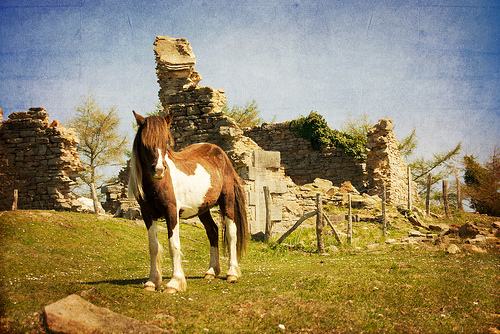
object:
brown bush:
[462, 145, 499, 217]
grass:
[161, 260, 323, 307]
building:
[0, 35, 417, 237]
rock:
[312, 178, 333, 191]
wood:
[262, 186, 271, 244]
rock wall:
[0, 107, 105, 215]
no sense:
[322, 131, 382, 159]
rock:
[397, 202, 500, 255]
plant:
[335, 246, 424, 316]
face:
[141, 126, 166, 165]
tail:
[218, 174, 249, 263]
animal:
[128, 110, 249, 294]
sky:
[0, 0, 499, 215]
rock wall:
[262, 139, 358, 187]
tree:
[341, 103, 464, 196]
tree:
[65, 86, 132, 214]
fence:
[262, 167, 464, 255]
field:
[0, 200, 499, 334]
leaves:
[273, 263, 366, 280]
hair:
[141, 115, 175, 151]